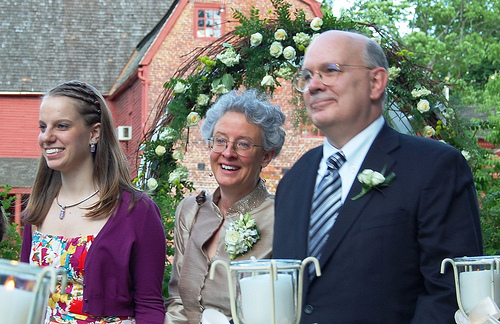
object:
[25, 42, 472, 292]
celebration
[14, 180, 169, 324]
sweater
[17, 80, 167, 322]
woman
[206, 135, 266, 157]
glasses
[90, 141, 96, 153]
earring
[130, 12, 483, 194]
arch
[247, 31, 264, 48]
flowers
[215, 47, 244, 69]
flowers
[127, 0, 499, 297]
arch way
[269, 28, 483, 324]
man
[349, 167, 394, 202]
flower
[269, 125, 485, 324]
suit jacket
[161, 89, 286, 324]
person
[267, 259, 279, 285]
handle part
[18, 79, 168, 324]
person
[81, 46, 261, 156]
wall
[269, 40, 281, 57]
flower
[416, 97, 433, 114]
flower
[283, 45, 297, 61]
flower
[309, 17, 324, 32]
flower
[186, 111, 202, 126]
flower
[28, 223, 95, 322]
dress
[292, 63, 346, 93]
glasses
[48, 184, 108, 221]
necklace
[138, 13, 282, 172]
wicker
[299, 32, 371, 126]
face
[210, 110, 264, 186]
face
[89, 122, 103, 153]
ear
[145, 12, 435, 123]
wreath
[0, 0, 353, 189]
building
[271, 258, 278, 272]
part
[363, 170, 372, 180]
part